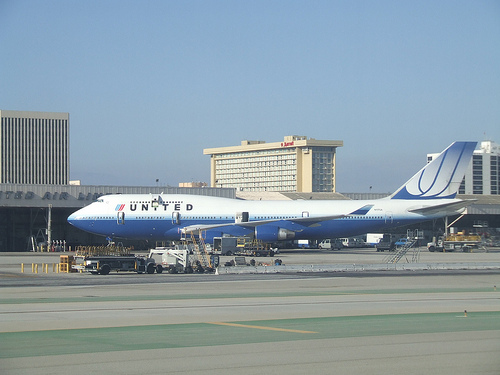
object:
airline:
[65, 141, 482, 260]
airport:
[4, 163, 499, 264]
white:
[205, 200, 225, 214]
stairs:
[176, 223, 214, 273]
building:
[202, 137, 340, 194]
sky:
[1, 4, 498, 71]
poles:
[20, 264, 25, 273]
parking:
[6, 267, 123, 292]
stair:
[381, 229, 420, 264]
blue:
[69, 217, 431, 243]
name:
[130, 203, 192, 212]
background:
[4, 97, 498, 193]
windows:
[136, 217, 137, 219]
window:
[106, 217, 107, 219]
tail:
[379, 141, 478, 224]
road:
[27, 239, 483, 260]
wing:
[185, 203, 373, 233]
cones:
[82, 247, 87, 258]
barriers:
[73, 239, 133, 259]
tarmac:
[70, 242, 498, 289]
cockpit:
[93, 198, 101, 202]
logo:
[113, 204, 125, 213]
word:
[43, 192, 51, 200]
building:
[6, 180, 499, 249]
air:
[43, 190, 70, 199]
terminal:
[1, 180, 248, 257]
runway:
[308, 239, 495, 271]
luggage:
[213, 236, 238, 253]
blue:
[172, 44, 221, 76]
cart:
[73, 254, 161, 274]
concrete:
[46, 296, 250, 313]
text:
[186, 203, 193, 210]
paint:
[345, 313, 375, 342]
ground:
[0, 281, 498, 358]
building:
[1, 107, 71, 184]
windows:
[10, 145, 11, 148]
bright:
[108, 71, 230, 140]